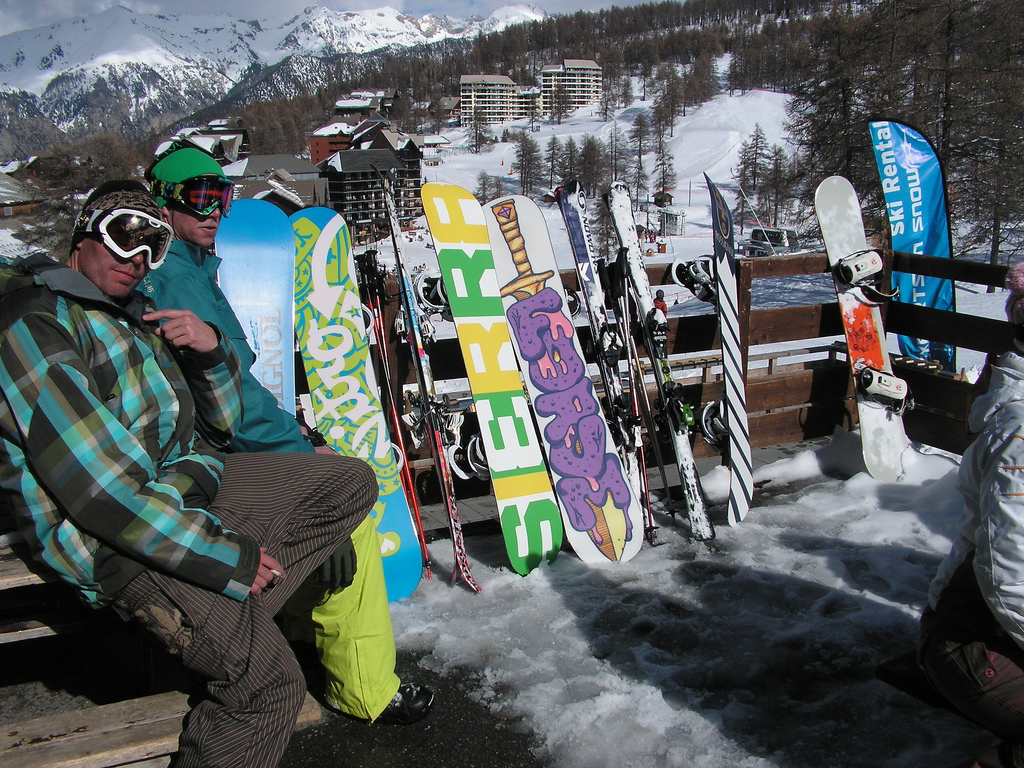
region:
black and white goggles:
[82, 205, 181, 269]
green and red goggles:
[161, 178, 247, 217]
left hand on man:
[139, 289, 220, 359]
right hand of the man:
[239, 536, 291, 606]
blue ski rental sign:
[869, 112, 993, 357]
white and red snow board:
[786, 157, 927, 480]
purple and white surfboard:
[486, 192, 645, 575]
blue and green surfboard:
[283, 200, 438, 615]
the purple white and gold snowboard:
[487, 186, 643, 564]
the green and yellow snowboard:
[424, 177, 576, 574]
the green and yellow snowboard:
[285, 202, 423, 605]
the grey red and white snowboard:
[814, 167, 919, 491]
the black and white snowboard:
[705, 171, 766, 522]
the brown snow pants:
[93, 431, 369, 761]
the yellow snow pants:
[308, 502, 401, 722]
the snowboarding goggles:
[71, 205, 174, 267]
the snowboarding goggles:
[147, 168, 236, 210]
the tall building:
[459, 69, 517, 134]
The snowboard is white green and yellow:
[375, 152, 606, 593]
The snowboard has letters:
[412, 162, 589, 606]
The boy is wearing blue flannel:
[5, 154, 470, 766]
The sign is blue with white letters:
[841, 104, 993, 434]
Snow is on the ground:
[392, 439, 1004, 727]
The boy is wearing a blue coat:
[115, 211, 347, 478]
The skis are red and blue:
[348, 148, 541, 616]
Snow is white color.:
[647, 105, 739, 211]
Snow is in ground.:
[637, 81, 774, 218]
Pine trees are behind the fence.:
[689, 7, 1002, 189]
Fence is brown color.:
[629, 241, 904, 504]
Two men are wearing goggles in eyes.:
[78, 132, 241, 339]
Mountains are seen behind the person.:
[2, 14, 414, 138]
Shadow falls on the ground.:
[392, 476, 943, 758]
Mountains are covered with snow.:
[13, 18, 209, 64]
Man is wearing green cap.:
[132, 127, 243, 252]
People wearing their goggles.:
[24, 136, 399, 757]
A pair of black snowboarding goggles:
[66, 205, 175, 275]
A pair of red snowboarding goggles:
[159, 171, 239, 217]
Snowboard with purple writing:
[489, 199, 663, 570]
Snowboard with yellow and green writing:
[410, 159, 572, 584]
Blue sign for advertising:
[867, 114, 963, 381]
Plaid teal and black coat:
[4, 275, 289, 612]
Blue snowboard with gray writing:
[217, 190, 306, 431]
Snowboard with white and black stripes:
[701, 177, 762, 531]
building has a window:
[331, 137, 351, 145]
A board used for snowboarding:
[813, 172, 918, 482]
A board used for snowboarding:
[667, 171, 756, 527]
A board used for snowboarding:
[482, 194, 642, 564]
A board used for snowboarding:
[291, 204, 424, 604]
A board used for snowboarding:
[212, 196, 296, 424]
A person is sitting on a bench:
[3, 175, 380, 765]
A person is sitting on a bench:
[132, 141, 434, 727]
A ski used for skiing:
[381, 162, 481, 596]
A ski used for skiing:
[607, 178, 716, 546]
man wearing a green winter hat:
[150, 152, 231, 242]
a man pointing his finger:
[21, 190, 221, 371]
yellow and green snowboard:
[428, 180, 559, 563]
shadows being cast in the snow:
[566, 552, 924, 761]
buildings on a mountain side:
[454, 42, 601, 151]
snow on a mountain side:
[7, 7, 504, 109]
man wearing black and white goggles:
[74, 184, 173, 296]